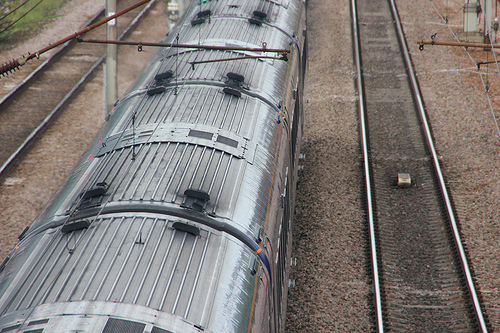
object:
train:
[0, 0, 310, 333]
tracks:
[387, 0, 489, 333]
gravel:
[299, 229, 363, 302]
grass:
[0, 0, 69, 38]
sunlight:
[238, 194, 258, 223]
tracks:
[0, 3, 108, 106]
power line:
[0, 0, 30, 22]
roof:
[0, 212, 262, 333]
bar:
[79, 38, 289, 52]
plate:
[95, 121, 248, 160]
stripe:
[212, 154, 235, 212]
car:
[0, 212, 286, 333]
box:
[396, 172, 412, 186]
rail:
[388, 0, 487, 333]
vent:
[188, 126, 214, 141]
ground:
[0, 0, 500, 333]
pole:
[103, 0, 120, 117]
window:
[274, 253, 286, 314]